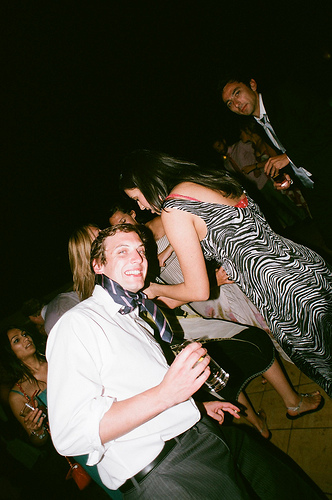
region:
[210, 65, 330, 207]
a man is in a suit holding a glass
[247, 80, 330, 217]
the black suit has a gray tie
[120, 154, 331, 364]
the girl has a black and white dress on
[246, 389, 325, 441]
the girl is wearing sandals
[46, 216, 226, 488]
the boy is partying in the crowd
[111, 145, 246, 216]
the woman has long black hair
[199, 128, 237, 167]
the man has a black beard in the background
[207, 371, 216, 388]
GLASS IN MAN HAND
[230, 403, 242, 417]
MAN HOLDING A CIGARETTE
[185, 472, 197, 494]
WHITE STRIPES IN PANTS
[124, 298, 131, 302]
PINK STRIPE IN TIE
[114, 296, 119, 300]
TIE HAS BLUE FOR BACKGROUND COLOR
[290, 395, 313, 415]
WOMAN HAS ON SANDALS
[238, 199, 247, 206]
WOMAN WEARING A RED BRA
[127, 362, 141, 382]
MAN HAS ON A WHITE SHIRT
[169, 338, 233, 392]
man holding glass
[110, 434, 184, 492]
man wearing black color belt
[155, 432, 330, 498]
man wearing black color pant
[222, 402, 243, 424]
man holding cigarette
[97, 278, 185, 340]
man wearing tie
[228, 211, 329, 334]
lady wearing black with white color dress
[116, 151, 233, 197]
woman having black color hair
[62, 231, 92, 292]
woman having silver color hair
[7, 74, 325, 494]
people at an event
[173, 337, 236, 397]
drink in man's hand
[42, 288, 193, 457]
shirt on man's body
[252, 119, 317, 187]
tie on the man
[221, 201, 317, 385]
dress on the woman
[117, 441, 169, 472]
belt on the man's waist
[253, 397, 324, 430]
sandals on the feet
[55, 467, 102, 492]
bag with the woman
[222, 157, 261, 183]
tie on the man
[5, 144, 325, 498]
People dancing on the dance floor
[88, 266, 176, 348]
Tie around a guy's neck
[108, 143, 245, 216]
Woman has long dark hair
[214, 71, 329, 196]
Man is wearing a suit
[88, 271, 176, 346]
Stripes on a blue tie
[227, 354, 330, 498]
Tiles are on the floor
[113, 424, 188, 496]
A black leather belt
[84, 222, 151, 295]
The guy is smiling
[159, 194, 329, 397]
The dress is black and white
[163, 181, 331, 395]
A black and white dress and a red undergarment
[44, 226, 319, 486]
Boy posing in his suit and tie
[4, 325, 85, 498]
Girl in green dress holding a drink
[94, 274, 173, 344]
blue and gold striped tie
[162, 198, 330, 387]
black and white zebra print dress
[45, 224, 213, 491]
man in white dress shirt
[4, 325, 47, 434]
woman holding cocktail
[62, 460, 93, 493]
dark red handbag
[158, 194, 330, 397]
black and white cocktail dress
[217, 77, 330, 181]
man in a dark suit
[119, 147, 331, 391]
woman in black and white dress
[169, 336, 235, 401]
glass of a drink being held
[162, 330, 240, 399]
glass of a drink being held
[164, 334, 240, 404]
glass of a drink being held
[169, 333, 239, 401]
glass of a drink being held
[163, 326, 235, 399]
glass of a drink being held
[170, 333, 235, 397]
glass of a drink being held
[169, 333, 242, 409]
glass of a drink being held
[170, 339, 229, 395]
hand holding nearly empty glass